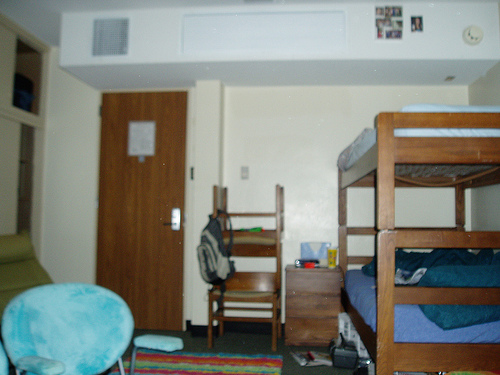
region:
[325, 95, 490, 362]
bunkbeds on side of wall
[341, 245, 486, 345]
blue bedding on lower bunk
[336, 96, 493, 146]
light blue bedding on upper bunk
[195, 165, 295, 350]
chair on top of another chair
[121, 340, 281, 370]
striped rug in bold colors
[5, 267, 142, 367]
chair covered in fuzzy blue material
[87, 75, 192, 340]
wooden door with sign on back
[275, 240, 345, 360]
night table with drawers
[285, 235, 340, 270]
red and yellow items placed on top of table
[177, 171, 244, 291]
backpack hanging from leg of chair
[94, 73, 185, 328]
a brown door to a room.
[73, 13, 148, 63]
an air conditioner vent.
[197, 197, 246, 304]
a backpack hanging on furniture.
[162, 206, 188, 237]
a silver colored door knob.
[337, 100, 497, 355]
a wooden bunk bed set.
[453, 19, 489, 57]
a white fire alarm.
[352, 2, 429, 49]
some pictures on the wall.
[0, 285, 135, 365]
a blue chair with round shape.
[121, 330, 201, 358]
blue arm rest of a chair.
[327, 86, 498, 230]
upper bunk of a bunk bed.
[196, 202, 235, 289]
Back pack hanging on a chair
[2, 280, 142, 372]
Blue circular chair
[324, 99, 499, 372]
Bunk beds against the wall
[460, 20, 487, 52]
Smoke detector on the wall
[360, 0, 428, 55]
Collage of pictures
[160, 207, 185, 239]
Handle of the door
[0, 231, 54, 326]
Green chair behind the blue chair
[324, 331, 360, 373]
Black box with a handle on the ground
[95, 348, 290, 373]
Colorful rug on the floor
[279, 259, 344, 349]
Short dresser next to the bed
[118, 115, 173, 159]
white sign on door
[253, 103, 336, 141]
clear white walls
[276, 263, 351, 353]
small brown dresser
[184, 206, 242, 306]
back pack hanging off chair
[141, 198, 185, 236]
silver door opener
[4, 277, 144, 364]
shiny blue fabric on chair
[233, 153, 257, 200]
white electrical outlet on wall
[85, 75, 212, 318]
large brown wooden door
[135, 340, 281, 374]
green and red rug on floor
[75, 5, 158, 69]
small blue vent on wall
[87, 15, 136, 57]
Air vent mounted in the soffit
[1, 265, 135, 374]
Turquoise colored round folding chair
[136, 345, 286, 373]
Stripped rug on the floor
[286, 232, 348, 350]
Three drawer night stand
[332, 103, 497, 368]
Bunk beds with wooden frame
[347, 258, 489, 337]
Blue bedding on bottom bunk bed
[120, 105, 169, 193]
Sign taped to back of door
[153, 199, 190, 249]
Silver door hardware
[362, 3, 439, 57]
Personal pictures taped on white wall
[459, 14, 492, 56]
Fire alarm